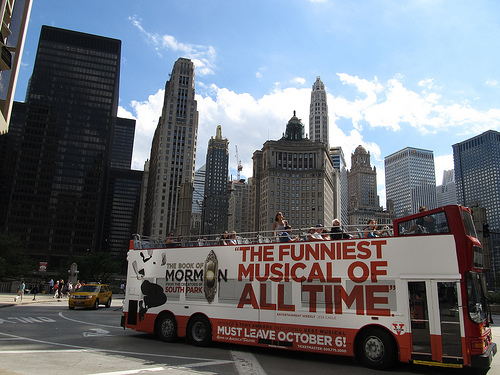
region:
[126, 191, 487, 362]
Tourist bus on the road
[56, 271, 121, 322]
yellow cab on the road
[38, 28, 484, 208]
different beautiful buildings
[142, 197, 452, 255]
passenger on the top of the bus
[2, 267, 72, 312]
people walking on the street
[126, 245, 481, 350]
advertisement on the building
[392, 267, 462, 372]
glass door of the bus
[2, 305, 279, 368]
signs on the road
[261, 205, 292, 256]
lady standing on top of the bus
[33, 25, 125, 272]
glass black building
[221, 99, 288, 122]
fluffy white clouds in the sky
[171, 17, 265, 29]
clear blue skies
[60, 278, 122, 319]
yellow taxi on the street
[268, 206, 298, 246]
woman on top of bus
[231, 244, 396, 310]
large red words on bus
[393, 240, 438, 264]
white surface on bus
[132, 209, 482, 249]
over head section on bus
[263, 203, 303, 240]
woman wearing short sleeve shirt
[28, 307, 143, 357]
white lines in street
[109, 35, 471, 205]
large sky scrapers in the sky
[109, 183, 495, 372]
Doubledecker bus has opened floor on top.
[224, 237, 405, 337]
Advertisement for a musical on bus.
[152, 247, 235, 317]
Advertisement for Book of Mormon on bus.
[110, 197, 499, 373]
Doubledecker bus is red and white.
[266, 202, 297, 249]
Woman is standing on upper level of bus.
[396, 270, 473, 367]
Doubledecker bus has two doors.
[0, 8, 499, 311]
There are tall buildings in the background.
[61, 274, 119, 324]
The yellow car is behind the bus.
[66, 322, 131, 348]
There's a white arrow painted on street.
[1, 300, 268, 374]
Street has several white lines painted on it.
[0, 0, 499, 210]
a cloudy blue sky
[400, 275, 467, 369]
a pair of bus doors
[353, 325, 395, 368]
a black and gray wheel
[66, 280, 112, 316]
a yellow car on the road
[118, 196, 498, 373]
a red and white bus on the road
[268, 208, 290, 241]
a woman on the bus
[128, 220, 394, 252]
the railing on the roof of the bus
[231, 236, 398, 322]
red writing on the bus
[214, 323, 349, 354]
white writing on the bus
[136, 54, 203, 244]
a tall gray building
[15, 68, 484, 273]
tall city skyscrapers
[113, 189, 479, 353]
tourist bus on street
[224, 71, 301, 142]
large white clouds in blue sky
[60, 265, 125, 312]
yellow taxi on road behind bus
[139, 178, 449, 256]
people on top of bus with no roof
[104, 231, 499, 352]
red and white tourist bus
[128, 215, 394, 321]
advertisement for musical on side of bus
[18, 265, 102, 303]
people walking on sidewalk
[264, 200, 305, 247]
woman standing up on top of bus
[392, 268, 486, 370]
two doors of bus